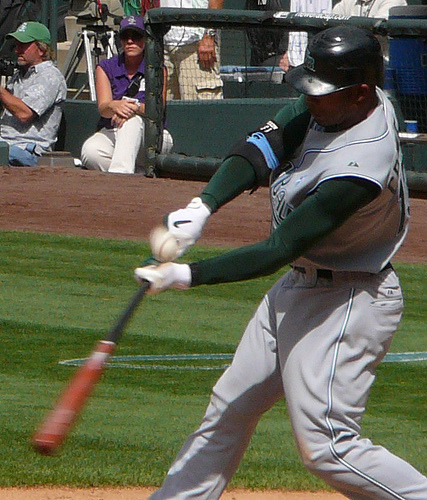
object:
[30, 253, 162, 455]
baseball bat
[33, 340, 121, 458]
color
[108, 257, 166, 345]
color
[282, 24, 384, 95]
helmet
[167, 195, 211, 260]
glove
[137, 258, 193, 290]
glove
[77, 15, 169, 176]
woman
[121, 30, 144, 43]
sunglasses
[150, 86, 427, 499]
uniform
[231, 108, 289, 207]
arm brace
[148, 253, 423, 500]
pants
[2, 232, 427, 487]
grass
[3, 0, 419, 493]
sport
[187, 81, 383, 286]
under shirt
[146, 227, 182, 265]
baseball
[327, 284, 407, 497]
stripe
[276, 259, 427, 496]
leg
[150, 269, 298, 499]
leg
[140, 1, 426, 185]
railing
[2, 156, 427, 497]
baseball field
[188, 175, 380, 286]
arm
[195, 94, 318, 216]
arm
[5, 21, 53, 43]
ball cap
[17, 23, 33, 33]
writing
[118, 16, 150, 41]
ball cap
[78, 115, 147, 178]
pants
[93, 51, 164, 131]
shirt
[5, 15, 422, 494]
game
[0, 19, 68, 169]
man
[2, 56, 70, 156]
shirt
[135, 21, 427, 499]
baseball player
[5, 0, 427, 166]
dugout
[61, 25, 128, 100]
tripod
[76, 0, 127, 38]
camera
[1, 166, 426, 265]
patch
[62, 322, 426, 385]
home base